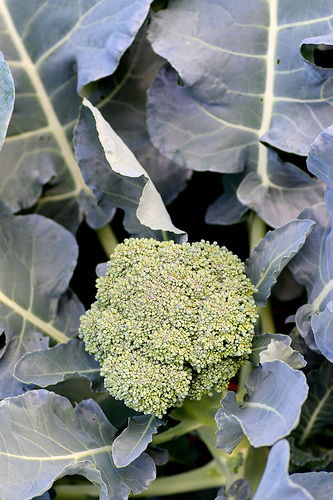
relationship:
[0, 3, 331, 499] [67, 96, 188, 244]
broccoli has leaf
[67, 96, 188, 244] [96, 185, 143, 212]
leaf has vein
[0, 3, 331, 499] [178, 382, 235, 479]
broccoli has stem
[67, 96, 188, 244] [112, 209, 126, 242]
leaf near dark space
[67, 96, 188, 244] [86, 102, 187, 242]
leaf has underside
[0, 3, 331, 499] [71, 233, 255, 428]
broccoli has floret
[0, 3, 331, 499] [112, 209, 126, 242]
broccoli near dark space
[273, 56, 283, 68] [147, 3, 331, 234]
spot on top of leaf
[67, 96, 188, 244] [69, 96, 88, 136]
leaf has edge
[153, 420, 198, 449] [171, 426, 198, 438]
stalk has edge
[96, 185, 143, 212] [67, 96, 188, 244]
vein inside leaf